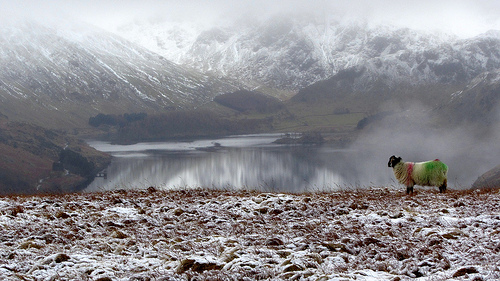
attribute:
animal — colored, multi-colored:
[382, 147, 455, 200]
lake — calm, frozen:
[82, 131, 391, 198]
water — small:
[93, 138, 379, 188]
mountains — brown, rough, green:
[4, 3, 499, 118]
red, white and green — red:
[402, 158, 448, 187]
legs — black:
[404, 185, 448, 194]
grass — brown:
[4, 185, 487, 203]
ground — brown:
[1, 187, 499, 279]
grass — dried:
[24, 191, 442, 274]